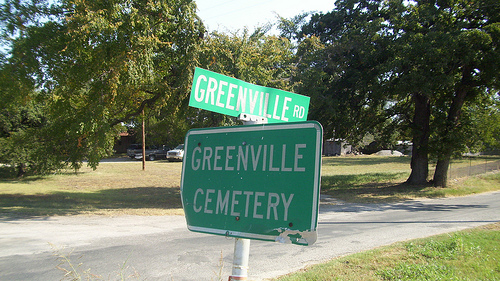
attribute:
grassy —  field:
[278, 215, 498, 279]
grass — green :
[366, 219, 488, 279]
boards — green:
[184, 65, 323, 254]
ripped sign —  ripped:
[253, 212, 333, 262]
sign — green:
[171, 61, 350, 120]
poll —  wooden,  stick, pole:
[130, 68, 156, 180]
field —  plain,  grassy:
[7, 159, 199, 223]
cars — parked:
[126, 125, 191, 173]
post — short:
[146, 49, 392, 259]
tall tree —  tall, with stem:
[293, 1, 498, 192]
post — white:
[225, 236, 256, 279]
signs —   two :
[175, 61, 330, 247]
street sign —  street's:
[193, 67, 314, 126]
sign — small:
[166, 110, 331, 238]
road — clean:
[2, 209, 242, 279]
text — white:
[169, 58, 340, 260]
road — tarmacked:
[42, 223, 149, 271]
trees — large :
[278, 30, 495, 230]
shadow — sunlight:
[320, 172, 489, 210]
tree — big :
[322, 0, 499, 193]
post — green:
[182, 68, 321, 247]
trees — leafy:
[292, 0, 470, 188]